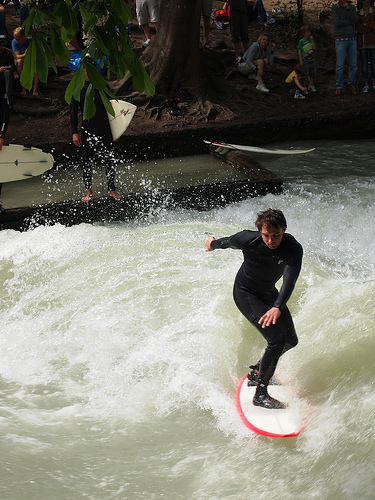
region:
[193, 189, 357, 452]
man surfing on indoor wave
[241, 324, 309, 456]
white and red surfboard on water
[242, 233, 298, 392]
black wet suit on man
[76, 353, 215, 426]
white water on waves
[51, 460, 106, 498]
white foam floating in water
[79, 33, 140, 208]
man on side holding board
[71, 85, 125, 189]
black wet suit on man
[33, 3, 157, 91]
green leaves over water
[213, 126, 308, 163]
white surf board on ground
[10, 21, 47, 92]
person in blue in background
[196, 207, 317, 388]
Surfwear in the photo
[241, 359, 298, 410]
Shoes in the photo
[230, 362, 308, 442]
A surfboard in the water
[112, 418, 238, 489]
Water in the ocean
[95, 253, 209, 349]
Waves in the ocean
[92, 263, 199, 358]
Water splashed in the sea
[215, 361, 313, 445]
A red and white surfboard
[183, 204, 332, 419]
Surfing in the waters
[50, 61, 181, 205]
A person holding a surfboard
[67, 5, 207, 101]
A tree in the photo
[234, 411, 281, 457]
edge of a board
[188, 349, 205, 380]
part of a splash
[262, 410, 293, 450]
part of a board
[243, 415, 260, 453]
part of an edge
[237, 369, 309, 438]
White surfboard with red trim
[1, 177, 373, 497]
Choppy waves in a wave pool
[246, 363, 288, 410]
Black shoes on surfer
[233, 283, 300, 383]
Black leggings on surfer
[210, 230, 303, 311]
Black rashguard on surfer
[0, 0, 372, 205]
Spectators in the background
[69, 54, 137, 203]
A surfer waiting beside the pool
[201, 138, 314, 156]
White surboard sitting to the side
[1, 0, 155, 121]
Tree leaves hanging at the top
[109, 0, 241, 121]
Large tree trunk with roots exposed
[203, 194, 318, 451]
person on a board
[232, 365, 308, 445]
board in the water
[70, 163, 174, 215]
splashes of water in air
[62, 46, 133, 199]
person holding a board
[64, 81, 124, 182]
wet suit on person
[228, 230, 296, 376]
wet suit on a person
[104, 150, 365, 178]
concrete area near water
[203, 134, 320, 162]
board on a log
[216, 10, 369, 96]
people observing surfing in water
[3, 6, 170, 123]
branches hanging from tree